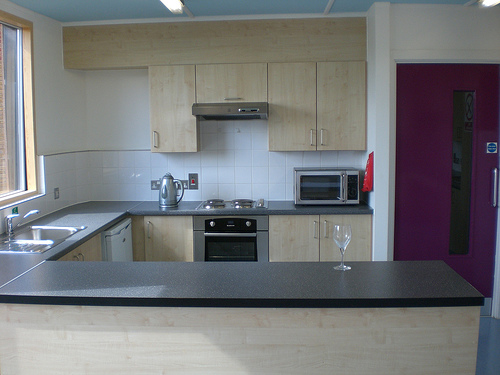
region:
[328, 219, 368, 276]
this is a glass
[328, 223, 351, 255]
the glass is shinny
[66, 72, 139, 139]
this is the wall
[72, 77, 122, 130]
the wall is white in color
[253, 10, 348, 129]
this is a cupboard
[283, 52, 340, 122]
the cupboard is wooden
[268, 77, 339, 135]
the cupboard is brown in color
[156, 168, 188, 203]
this is a kettle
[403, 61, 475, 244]
this is the door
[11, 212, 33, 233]
this is a tap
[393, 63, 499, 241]
a purple door is next to the kitchen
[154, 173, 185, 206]
a silver coffee pot is on the counter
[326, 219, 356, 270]
an empty wine glass in on the counter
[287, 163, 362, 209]
a microwave is next to the stove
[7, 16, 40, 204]
the window is closed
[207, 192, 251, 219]
there are four burners on the stove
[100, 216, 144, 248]
a dishwasher is next to the sink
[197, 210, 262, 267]
the over is under the stove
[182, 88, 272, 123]
a hood vent is above the stove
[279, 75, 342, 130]
the cabinets are made of wood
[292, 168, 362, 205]
Microwave oven on a counter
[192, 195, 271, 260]
Electric stove in a room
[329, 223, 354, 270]
A glass on a counter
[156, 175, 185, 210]
A thermos pitcher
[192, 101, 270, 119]
Over the range fan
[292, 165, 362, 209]
A microwave on a countertop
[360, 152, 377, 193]
red mitten for cooking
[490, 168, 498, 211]
Door handle on a purple door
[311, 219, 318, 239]
Metal handle on a cabinet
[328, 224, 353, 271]
A wine glass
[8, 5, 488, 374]
A kitchen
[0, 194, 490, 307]
Black countertops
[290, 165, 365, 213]
A silver and black microwave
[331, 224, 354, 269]
A clear wine glass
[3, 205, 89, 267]
A silver sink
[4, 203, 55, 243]
Silver sink fixtures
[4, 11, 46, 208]
A window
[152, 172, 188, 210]
A tall silver tea kettle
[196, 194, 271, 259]
A silver and black stove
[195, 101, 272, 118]
A silver over the stove exhaust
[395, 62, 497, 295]
Purple door with a long glass window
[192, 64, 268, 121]
Stainless steel range hood under cabinet door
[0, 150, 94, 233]
White tile back splash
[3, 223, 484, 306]
Empty wine glass a gray counter with light specks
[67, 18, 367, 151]
Light wood grain upper cabinets with silver handles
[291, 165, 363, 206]
Stainless steel finish microwave oven with black control panel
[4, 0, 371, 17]
Portion of a blue ceiling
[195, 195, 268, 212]
Range top with black burner covers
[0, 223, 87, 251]
Stainless steel sink and drain panel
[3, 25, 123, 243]
Sunlight shining through a kitchen window